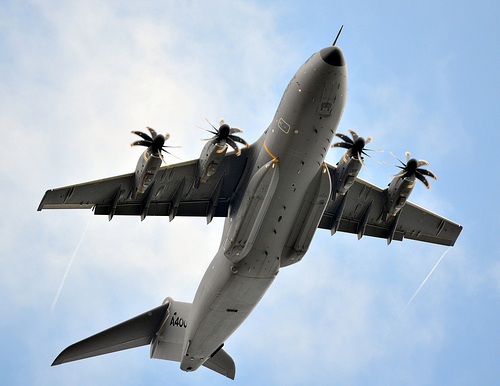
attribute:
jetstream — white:
[44, 209, 97, 317]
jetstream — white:
[401, 241, 455, 317]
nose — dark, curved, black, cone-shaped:
[317, 47, 345, 71]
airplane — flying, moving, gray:
[32, 27, 464, 382]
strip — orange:
[255, 136, 279, 171]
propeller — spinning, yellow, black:
[132, 124, 180, 164]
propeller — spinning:
[200, 117, 253, 162]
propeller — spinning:
[330, 124, 378, 174]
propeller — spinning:
[388, 148, 438, 188]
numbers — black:
[167, 310, 194, 333]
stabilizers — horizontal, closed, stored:
[222, 152, 335, 273]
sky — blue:
[3, 4, 497, 384]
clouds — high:
[40, 23, 336, 293]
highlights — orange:
[239, 122, 355, 181]